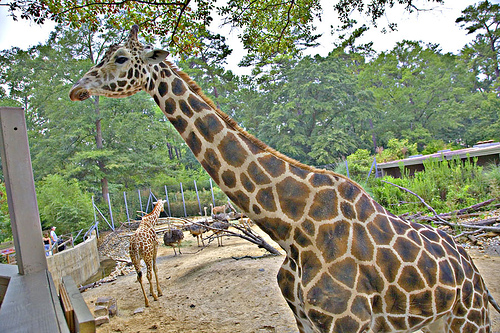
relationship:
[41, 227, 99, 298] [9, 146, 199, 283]
brick wall in background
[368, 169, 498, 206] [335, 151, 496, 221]
branchges in background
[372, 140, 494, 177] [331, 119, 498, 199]
structure in background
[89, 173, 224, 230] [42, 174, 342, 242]
metal poles in background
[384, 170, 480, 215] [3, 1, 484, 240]
weeds in background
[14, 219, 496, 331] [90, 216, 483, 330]
dirt covering ground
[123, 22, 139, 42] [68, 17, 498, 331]
horns on giraffe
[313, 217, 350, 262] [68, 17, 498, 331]
spot on giraffe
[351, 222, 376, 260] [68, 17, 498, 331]
spot on giraffe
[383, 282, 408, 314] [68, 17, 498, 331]
spot on giraffe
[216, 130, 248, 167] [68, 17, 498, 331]
spot on giraffe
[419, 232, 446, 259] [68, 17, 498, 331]
spot on giraffe